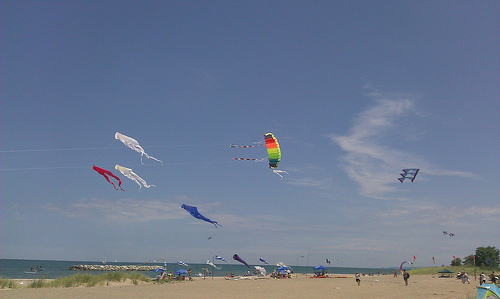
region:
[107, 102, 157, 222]
kites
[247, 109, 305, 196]
kite in air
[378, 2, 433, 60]
white clouds in blue sky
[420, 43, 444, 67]
white clouds in blue sky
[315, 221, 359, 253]
white clouds in blue sky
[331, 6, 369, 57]
white clouds in blue sky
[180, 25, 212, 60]
white clouds in blue sky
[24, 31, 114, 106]
white clouds in blue sky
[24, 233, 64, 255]
white clouds in blue sky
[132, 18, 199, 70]
white clouds in blue sky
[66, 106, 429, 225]
the kites are in the air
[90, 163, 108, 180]
the kite is red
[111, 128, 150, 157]
the kite is white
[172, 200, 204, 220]
the kite is blue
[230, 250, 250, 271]
the wind sock is purple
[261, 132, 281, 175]
the kite is multi color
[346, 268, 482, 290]
the people are on the beach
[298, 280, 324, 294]
the sand is tan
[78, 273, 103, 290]
grass is growing through the sand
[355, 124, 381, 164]
clouds are in the sky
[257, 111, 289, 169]
kite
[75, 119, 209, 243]
kites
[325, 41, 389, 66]
white clouds in blue sky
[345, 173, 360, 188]
white clouds in blue sky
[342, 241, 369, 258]
white clouds in blue sky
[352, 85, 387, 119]
white clouds in blue sky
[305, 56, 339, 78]
white clouds in blue sky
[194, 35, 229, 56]
white clouds in blue sky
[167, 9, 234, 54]
white clouds in blue sky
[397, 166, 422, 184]
kite flying in sky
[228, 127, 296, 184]
kite flying in sky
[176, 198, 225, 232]
kite flying in sky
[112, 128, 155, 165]
kite flying in sky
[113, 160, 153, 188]
kite flying in sky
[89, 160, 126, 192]
kite flying in sky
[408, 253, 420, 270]
kite flying in sky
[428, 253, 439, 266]
kite flying in sky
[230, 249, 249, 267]
kite flying in sky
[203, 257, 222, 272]
kite flying in sky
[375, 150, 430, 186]
kite in the sky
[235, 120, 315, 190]
kite in the sky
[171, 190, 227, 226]
kite in the sky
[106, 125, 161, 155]
kite in the sky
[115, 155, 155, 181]
kite in the sky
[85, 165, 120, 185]
kite in the sky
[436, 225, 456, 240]
kite in the sky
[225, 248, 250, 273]
kite in the sky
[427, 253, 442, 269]
kite in the sky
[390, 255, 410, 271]
kite in the sky